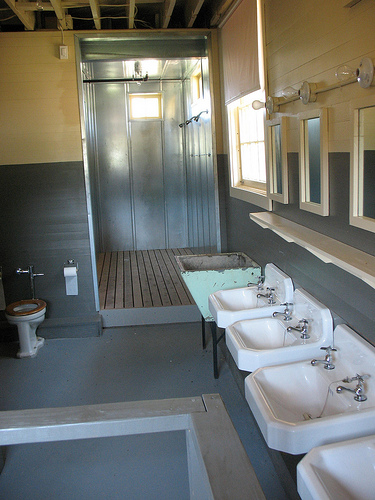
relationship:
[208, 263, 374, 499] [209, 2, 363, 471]
sinks on wall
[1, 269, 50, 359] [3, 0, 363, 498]
toilet in bathroom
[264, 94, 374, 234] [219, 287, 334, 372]
mirrors above sink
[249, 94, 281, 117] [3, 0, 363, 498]
light in bathroom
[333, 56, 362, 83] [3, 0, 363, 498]
bulb in bathroom